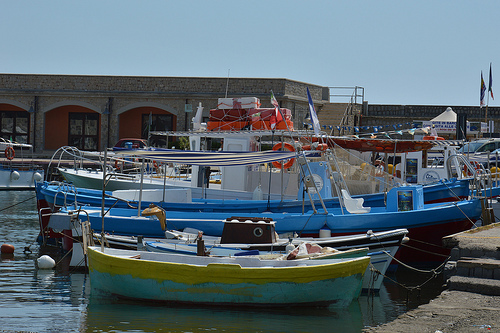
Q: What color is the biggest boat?
A: Blue.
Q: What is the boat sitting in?
A: Water.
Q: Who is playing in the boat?
A: No one.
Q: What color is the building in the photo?
A: Brown.